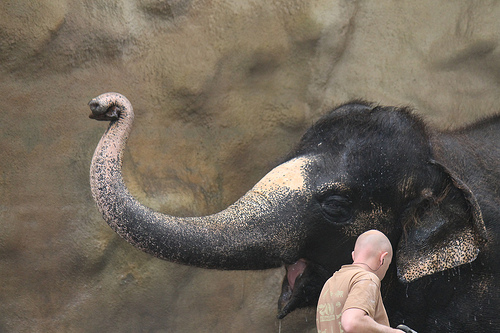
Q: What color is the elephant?
A: Black.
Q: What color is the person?
A: White.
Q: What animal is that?
A: Elephant.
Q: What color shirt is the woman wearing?
A: Tan.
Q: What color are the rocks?
A: Brown.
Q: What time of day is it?
A: Afternoon.